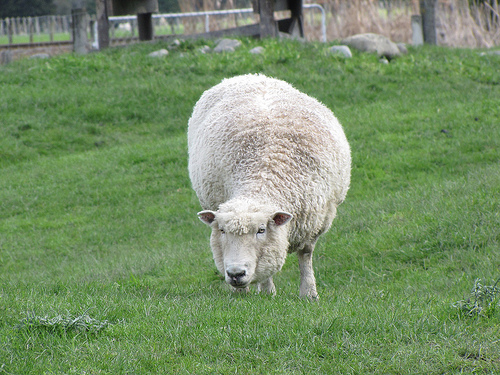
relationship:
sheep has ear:
[187, 70, 352, 299] [197, 209, 219, 226]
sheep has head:
[187, 70, 352, 299] [196, 198, 294, 289]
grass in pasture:
[355, 171, 461, 317] [1, 1, 499, 371]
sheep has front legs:
[187, 70, 352, 299] [249, 235, 321, 307]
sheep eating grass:
[187, 70, 352, 299] [0, 37, 497, 373]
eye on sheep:
[255, 227, 266, 237] [187, 70, 352, 299]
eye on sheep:
[216, 226, 229, 235] [187, 70, 352, 299]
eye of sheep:
[216, 226, 229, 235] [187, 70, 352, 299]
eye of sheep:
[255, 227, 263, 234] [187, 70, 352, 299]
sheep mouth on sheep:
[229, 275, 253, 289] [187, 70, 352, 299]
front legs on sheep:
[298, 235, 321, 300] [187, 70, 352, 299]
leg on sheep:
[256, 271, 272, 295] [187, 70, 352, 299]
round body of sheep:
[184, 72, 350, 251] [187, 70, 352, 299]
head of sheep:
[191, 198, 300, 298] [187, 70, 352, 299]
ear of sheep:
[269, 205, 291, 232] [187, 70, 352, 299]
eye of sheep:
[255, 227, 266, 237] [98, 40, 383, 350]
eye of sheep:
[216, 226, 229, 235] [180, 60, 364, 312]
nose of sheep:
[226, 266, 247, 280] [163, 0, 450, 320]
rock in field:
[343, 27, 403, 61] [3, 40, 493, 372]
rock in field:
[318, 41, 356, 62] [3, 40, 493, 372]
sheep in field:
[187, 70, 352, 299] [3, 40, 493, 372]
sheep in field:
[170, 44, 347, 335] [3, 40, 493, 372]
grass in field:
[0, 37, 497, 373] [3, 40, 493, 372]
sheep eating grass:
[170, 44, 347, 335] [0, 37, 497, 373]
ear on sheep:
[269, 210, 295, 226] [187, 70, 352, 299]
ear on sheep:
[194, 209, 219, 226] [187, 70, 352, 299]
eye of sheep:
[255, 227, 266, 237] [187, 70, 352, 299]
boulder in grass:
[339, 32, 401, 59] [0, 37, 497, 373]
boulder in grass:
[323, 42, 355, 60] [0, 37, 497, 373]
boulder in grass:
[213, 33, 240, 56] [0, 37, 497, 373]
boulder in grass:
[247, 45, 265, 54] [0, 37, 497, 373]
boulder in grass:
[329, 46, 353, 56] [0, 37, 497, 373]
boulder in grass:
[345, 31, 401, 56] [0, 37, 497, 373]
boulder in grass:
[213, 37, 240, 49] [0, 37, 497, 373]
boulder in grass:
[194, 43, 209, 52] [0, 37, 497, 373]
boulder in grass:
[148, 48, 168, 58] [0, 37, 497, 373]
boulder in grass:
[173, 35, 181, 47] [0, 37, 497, 373]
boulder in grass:
[210, 37, 246, 56] [374, 50, 491, 372]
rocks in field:
[327, 30, 410, 63] [20, 63, 210, 318]